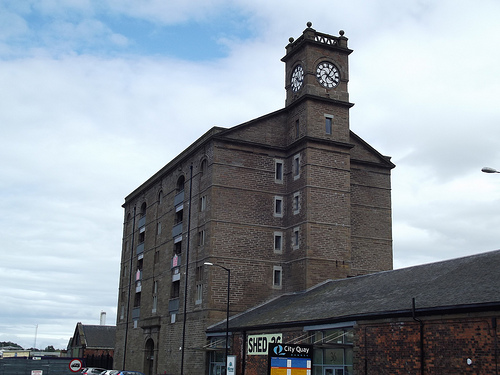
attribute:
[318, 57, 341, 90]
clock — white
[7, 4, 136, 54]
clouds — white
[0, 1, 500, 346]
sky — blue, overcast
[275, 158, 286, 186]
opening — small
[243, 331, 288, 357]
sign — business, white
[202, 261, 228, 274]
light — street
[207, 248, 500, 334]
roof — gray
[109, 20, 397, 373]
building — brick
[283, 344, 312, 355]
letters — white